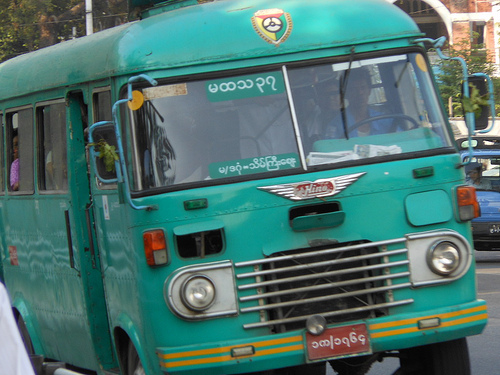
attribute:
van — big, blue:
[1, 0, 498, 375]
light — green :
[183, 196, 211, 213]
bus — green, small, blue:
[1, 2, 487, 374]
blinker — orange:
[130, 227, 184, 277]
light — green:
[177, 274, 217, 310]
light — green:
[227, 344, 257, 357]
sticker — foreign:
[202, 150, 304, 180]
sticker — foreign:
[200, 67, 287, 109]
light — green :
[440, 185, 487, 221]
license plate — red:
[299, 319, 372, 365]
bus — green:
[69, 33, 486, 354]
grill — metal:
[227, 241, 419, 332]